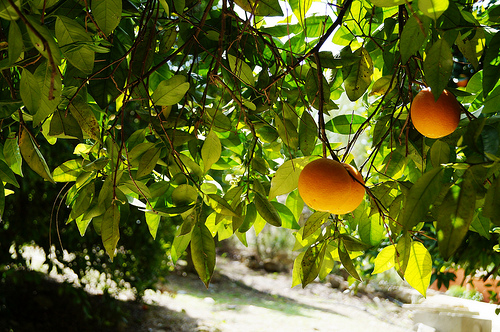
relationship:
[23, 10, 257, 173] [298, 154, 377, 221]
leaves next to orange